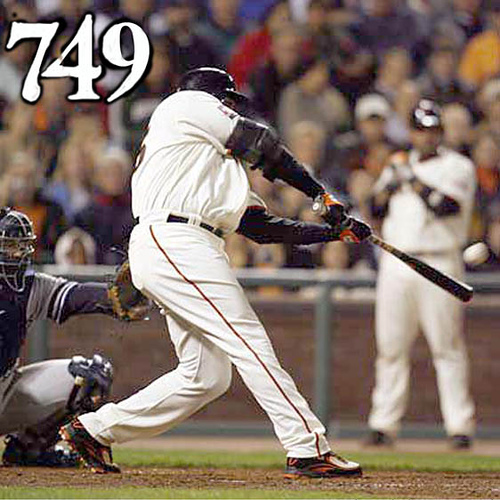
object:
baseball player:
[58, 65, 373, 477]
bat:
[311, 198, 475, 302]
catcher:
[0, 206, 153, 466]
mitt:
[107, 256, 156, 321]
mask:
[0, 209, 35, 294]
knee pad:
[68, 355, 113, 412]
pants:
[76, 211, 331, 461]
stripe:
[148, 224, 323, 458]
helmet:
[172, 66, 251, 102]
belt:
[131, 212, 223, 239]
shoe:
[58, 416, 122, 475]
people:
[70, 145, 140, 264]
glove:
[320, 189, 348, 229]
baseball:
[462, 241, 489, 267]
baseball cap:
[355, 93, 391, 122]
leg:
[129, 224, 325, 456]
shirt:
[131, 91, 249, 236]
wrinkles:
[138, 118, 250, 236]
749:
[6, 12, 151, 104]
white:
[158, 106, 190, 151]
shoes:
[284, 444, 363, 480]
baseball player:
[365, 97, 478, 449]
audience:
[274, 48, 356, 151]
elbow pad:
[226, 115, 308, 186]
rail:
[24, 263, 499, 438]